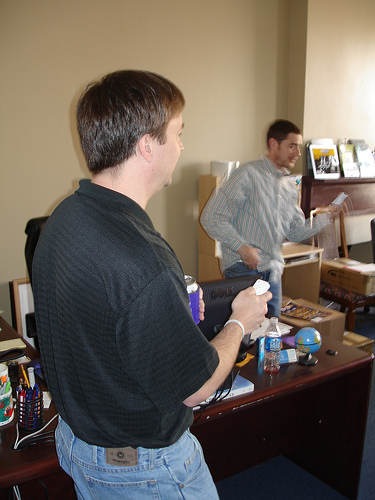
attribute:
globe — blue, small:
[294, 326, 323, 366]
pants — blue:
[54, 418, 222, 499]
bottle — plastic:
[260, 313, 284, 376]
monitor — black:
[197, 270, 269, 354]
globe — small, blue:
[294, 327, 324, 364]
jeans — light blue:
[30, 417, 266, 498]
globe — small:
[292, 325, 322, 357]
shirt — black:
[78, 203, 162, 288]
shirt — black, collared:
[32, 182, 214, 443]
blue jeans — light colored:
[61, 422, 206, 498]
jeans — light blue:
[91, 446, 185, 490]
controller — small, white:
[234, 276, 276, 332]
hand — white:
[229, 285, 273, 330]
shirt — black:
[40, 228, 193, 429]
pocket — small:
[170, 432, 212, 496]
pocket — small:
[226, 261, 259, 277]